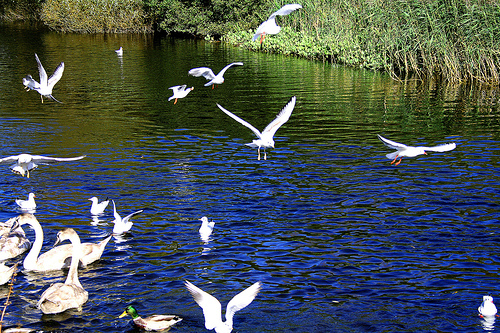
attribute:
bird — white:
[20, 52, 65, 102]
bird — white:
[1, 150, 86, 177]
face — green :
[118, 304, 139, 323]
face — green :
[125, 304, 137, 321]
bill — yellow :
[120, 313, 131, 322]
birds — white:
[184, 1, 461, 174]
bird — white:
[15, 51, 74, 112]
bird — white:
[161, 79, 199, 111]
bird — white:
[3, 49, 73, 111]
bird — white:
[3, 146, 91, 186]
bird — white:
[16, 48, 82, 110]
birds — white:
[76, 192, 224, 248]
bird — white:
[79, 191, 112, 229]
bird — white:
[103, 196, 148, 245]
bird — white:
[470, 289, 498, 324]